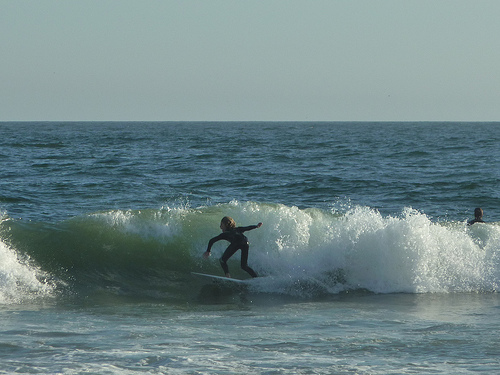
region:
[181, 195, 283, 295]
surfer riding a wave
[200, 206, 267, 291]
surfer wearing black wetsuit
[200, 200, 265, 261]
one arm angled down the other out to side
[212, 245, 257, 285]
knees bent over surfboard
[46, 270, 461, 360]
calm water in front of wave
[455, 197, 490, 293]
person's head and shoulders above wave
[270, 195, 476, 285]
white water splashing high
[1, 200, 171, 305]
slope of water through two waves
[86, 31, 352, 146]
solid gray sky above ocean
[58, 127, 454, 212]
empty ocean behind wave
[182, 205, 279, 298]
surfer riding on wave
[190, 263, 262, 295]
white surfboard surfer is riding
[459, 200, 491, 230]
person behind the wall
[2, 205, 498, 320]
white foam of wave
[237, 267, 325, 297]
trail the surfboard is making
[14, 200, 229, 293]
swell of the wave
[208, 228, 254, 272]
black wetsuit of surfer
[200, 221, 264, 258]
arms of the surfer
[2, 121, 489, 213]
still ocean behind surfer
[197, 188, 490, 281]
two people in the ocean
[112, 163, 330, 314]
person surfing some waves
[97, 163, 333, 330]
person surfing some nice waves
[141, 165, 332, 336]
person surfing some ocean waves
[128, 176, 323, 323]
person surfing some nice ocean waves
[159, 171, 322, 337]
person surfing some awesome waves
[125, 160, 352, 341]
person surfing huge waves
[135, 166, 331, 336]
person surfing large waves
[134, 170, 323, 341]
person surfing large ocean waves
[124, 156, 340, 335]
person surfing huge ocean waves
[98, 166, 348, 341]
person surfing great ocean waves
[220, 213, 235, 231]
The blonde hair of the surfer.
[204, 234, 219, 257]
The left arm of the surfer.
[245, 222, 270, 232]
The right arm of the surfer.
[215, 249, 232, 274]
The left leg of the surfer.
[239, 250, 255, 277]
The right leg of the surfer.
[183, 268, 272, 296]
The white surfboard.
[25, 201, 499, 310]
The wave the surfer is riding.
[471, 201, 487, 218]
The head of the person on the right.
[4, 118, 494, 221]
The water in the distance.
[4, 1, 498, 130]
The gray gloomy sky.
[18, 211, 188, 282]
A wave in the water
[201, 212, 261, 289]
A surfer riding a wave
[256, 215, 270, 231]
The left hand of the surfer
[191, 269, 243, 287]
The surfboard is white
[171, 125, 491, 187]
The water behind the wave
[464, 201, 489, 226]
A person behind the wave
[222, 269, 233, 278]
The right foot of the surfer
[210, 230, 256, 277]
The wetsuit is black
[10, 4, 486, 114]
The sky above the water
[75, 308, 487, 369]
The water in front of the wave